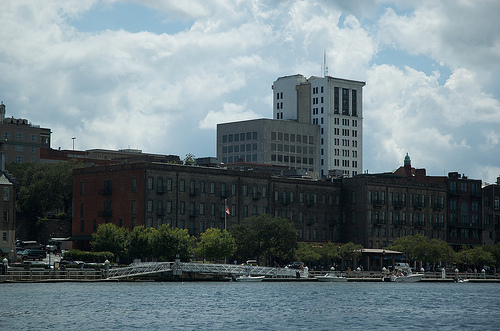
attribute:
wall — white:
[286, 90, 326, 197]